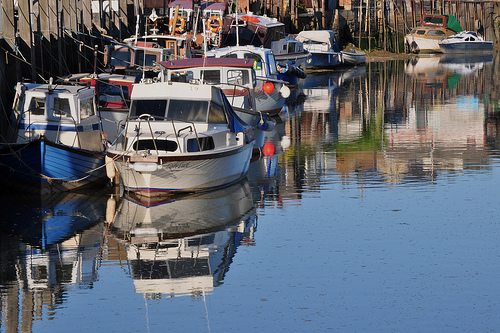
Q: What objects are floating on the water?
A: Boats.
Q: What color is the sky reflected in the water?
A: Blue.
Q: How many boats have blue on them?
A: One.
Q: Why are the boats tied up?
A: Will not float away.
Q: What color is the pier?
A: Brown.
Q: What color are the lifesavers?
A: Orange.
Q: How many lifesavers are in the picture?
A: Two.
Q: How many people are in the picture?
A: None.